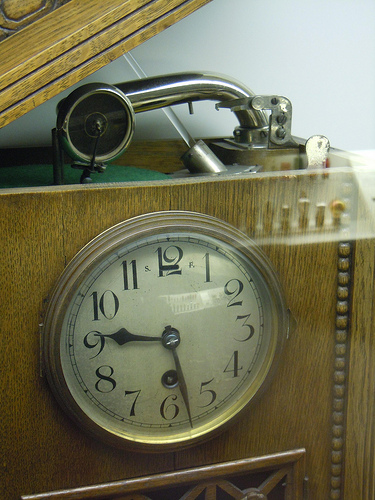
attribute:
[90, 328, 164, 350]
arm — black 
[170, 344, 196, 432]
arm — black 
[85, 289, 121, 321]
number — black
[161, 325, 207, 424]
hand — black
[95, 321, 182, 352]
hand — black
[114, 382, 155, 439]
number — black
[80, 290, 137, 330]
writing — black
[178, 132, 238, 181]
cylinder — short, round, grey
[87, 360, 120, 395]
number — black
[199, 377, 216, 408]
number — black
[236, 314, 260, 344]
number — black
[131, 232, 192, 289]
number — black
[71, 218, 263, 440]
numbers — black 